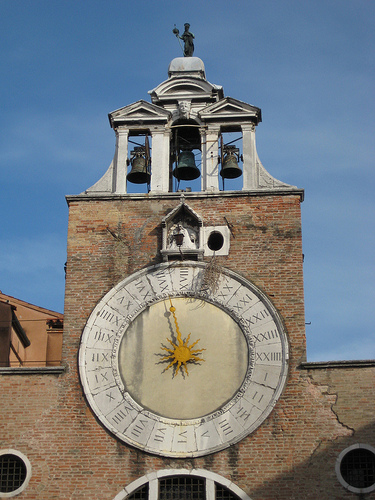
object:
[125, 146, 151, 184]
bell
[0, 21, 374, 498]
building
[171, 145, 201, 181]
bell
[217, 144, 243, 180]
bell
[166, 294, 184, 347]
hand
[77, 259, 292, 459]
clock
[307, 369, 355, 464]
crack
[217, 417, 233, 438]
roman numerals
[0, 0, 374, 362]
sky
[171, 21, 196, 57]
statue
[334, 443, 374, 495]
window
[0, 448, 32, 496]
window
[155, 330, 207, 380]
sun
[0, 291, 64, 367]
building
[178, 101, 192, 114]
face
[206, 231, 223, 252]
hole